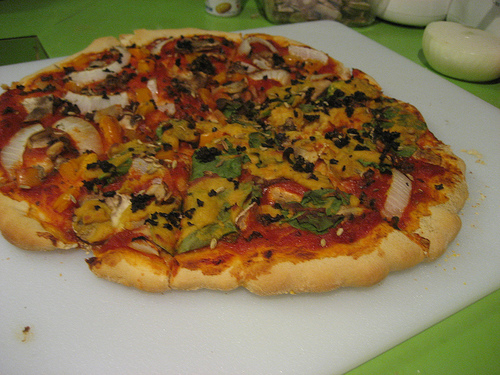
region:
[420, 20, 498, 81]
half of a yellow onion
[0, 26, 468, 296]
pizza with assorted vegetables and tomato sauce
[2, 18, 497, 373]
large white plastic cutting board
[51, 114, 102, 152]
slice of white onion on pizza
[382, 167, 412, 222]
slice of white onion on pizza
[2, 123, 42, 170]
slice of white onion on pizza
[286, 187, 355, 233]
wilted green spinach on pizza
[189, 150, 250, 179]
wilted green spinach on pizza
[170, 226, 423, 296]
crust of a slice of pizza with tomato sauce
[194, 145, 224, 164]
bunch of chopped black olives on pizza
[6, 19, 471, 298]
a pizza on a white cutting board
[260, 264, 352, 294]
the crust of a pizza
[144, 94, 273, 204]
the toppings of a pizza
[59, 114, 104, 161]
an onion on top of a pizza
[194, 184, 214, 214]
the melted cheese of a pizza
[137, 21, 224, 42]
the crust of a pizza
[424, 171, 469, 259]
the crust of a pizza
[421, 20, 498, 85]
a half onion on a table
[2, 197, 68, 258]
the crust of a pizza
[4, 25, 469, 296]
homemade pizza with uneven crust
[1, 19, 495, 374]
pizza on a white plastic cutting board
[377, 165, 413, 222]
large slice of onion on pizza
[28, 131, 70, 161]
mushrooms on homemade pizza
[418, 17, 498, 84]
cut onion on the counter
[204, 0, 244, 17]
bottom of a salt shaker on the table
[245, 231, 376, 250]
red pizza sauce on crust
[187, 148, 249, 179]
green spinach on pizza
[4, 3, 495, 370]
lime green counter top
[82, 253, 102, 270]
burnt edge of pizza crust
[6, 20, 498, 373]
a white plastic cutting board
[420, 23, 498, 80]
half of a white onion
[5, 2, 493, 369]
a green table cloth under the cutting board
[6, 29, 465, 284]
a thin crust pizza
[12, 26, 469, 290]
a pizza with tomato sauce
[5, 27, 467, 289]
a pizza cut in 8 slices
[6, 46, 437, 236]
tomato sauce on the pizza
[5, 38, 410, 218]
pieces of onion on the pizza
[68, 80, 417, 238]
green and yellow pepper on the pizza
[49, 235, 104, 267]
a chunk missing from the crust on the left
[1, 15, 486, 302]
Pizza is on the plate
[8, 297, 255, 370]
The tray is white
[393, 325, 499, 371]
This surface is green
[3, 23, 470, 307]
Pizza has no cheese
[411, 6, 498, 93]
Onion has been cut in half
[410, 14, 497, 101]
The onions are white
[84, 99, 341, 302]
There is mustard on the pizza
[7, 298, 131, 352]
Dirt on the plate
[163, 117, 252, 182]
The peepers are black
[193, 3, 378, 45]
Glass in the back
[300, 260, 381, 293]
crust of the pizza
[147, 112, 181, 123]
tomato on the pizza